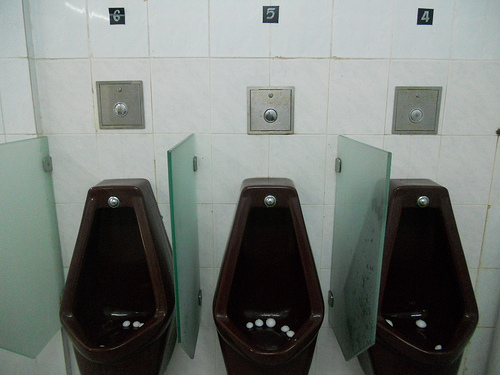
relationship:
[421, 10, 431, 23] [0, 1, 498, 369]
number on wall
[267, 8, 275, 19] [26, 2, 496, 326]
number on wall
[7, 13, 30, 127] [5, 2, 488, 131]
mirror on wall